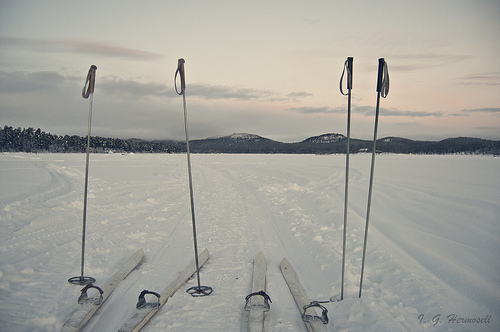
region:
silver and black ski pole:
[66, 50, 102, 285]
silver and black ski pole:
[165, 35, 209, 287]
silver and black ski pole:
[323, 51, 357, 295]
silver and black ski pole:
[359, 34, 394, 320]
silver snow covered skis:
[46, 220, 217, 330]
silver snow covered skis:
[233, 226, 329, 328]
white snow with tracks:
[14, 157, 68, 264]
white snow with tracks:
[210, 160, 317, 237]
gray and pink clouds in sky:
[199, 17, 306, 123]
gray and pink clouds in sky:
[405, 21, 477, 123]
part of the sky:
[231, 6, 310, 86]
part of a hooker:
[171, 210, 216, 278]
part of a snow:
[244, 200, 289, 236]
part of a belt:
[333, 69, 343, 86]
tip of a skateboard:
[274, 249, 294, 266]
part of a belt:
[256, 291, 268, 306]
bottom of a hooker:
[60, 270, 87, 287]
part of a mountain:
[230, 127, 278, 149]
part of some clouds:
[228, 79, 285, 107]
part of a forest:
[9, 130, 75, 160]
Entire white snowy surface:
[0, 151, 499, 329]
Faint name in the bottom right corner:
[414, 309, 496, 326]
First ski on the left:
[57, 248, 143, 328]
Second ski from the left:
[111, 246, 206, 326]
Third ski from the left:
[241, 251, 272, 330]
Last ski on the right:
[280, 258, 328, 329]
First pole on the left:
[68, 63, 96, 284]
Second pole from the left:
[173, 57, 211, 297]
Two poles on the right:
[338, 55, 388, 297]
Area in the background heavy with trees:
[0, 125, 183, 155]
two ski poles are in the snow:
[50, 55, 215, 330]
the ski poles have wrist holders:
[75, 57, 190, 100]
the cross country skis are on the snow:
[57, 240, 209, 325]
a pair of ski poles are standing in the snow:
[332, 55, 387, 300]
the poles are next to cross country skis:
[240, 52, 393, 327]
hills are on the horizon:
[5, 116, 495, 322]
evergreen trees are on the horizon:
[0, 112, 171, 159]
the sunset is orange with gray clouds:
[12, 6, 493, 172]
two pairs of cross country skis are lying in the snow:
[42, 240, 338, 330]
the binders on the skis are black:
[76, 278, 166, 314]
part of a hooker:
[316, 149, 351, 249]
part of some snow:
[216, 194, 269, 259]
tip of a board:
[265, 232, 300, 287]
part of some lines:
[151, 197, 186, 249]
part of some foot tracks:
[238, 163, 290, 232]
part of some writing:
[440, 292, 492, 325]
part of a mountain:
[228, 123, 263, 165]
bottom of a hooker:
[194, 285, 211, 299]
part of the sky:
[402, 62, 440, 107]